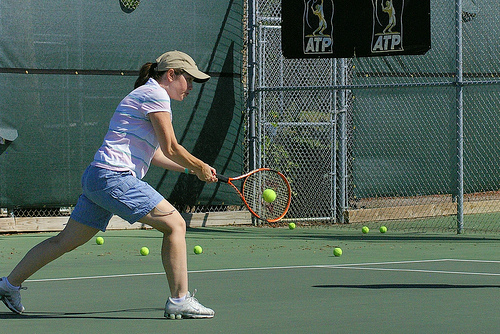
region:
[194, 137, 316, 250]
orange tennis racket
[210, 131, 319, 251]
orange tennis racket hitting tennis ball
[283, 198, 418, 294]
tennis balls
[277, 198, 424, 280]
tennis balls on tennis court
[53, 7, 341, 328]
woman tennis player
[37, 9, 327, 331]
woman hitting tennis balls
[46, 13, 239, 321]
woman wearing baseball hat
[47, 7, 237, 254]
woman wearing shorts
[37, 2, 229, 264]
woman wearing striped shirt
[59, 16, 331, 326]
woman tennis player wearing short sleaved shirt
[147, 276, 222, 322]
the shoe is white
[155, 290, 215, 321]
the shoe is on the court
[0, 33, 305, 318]
the woman is holding the racket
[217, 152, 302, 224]
the racket is red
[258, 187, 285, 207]
the ball is green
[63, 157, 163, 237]
the shorts are blue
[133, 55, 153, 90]
the hair is in a ponytail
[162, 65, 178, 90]
the girl has an ear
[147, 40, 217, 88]
the cap is brown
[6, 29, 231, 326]
the girl is wearing a cap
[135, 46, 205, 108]
the head of a woman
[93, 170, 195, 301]
the leg of a woman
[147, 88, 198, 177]
the arm of a woman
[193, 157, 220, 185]
the hands of a woman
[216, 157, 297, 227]
an orange tennis racket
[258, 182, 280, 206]
a green tennis ball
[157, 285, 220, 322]
a gray tennis shoe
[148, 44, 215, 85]
a tan baseball cap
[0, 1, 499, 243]
a gray chain link fence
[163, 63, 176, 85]
the ear of a woman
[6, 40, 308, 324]
woman playing tennis on court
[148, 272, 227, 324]
white tennis shoes on green court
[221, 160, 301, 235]
orange racket hitting ball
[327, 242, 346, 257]
bright green tennis ball on ground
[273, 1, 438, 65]
black banner on fence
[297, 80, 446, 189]
chain link fence around court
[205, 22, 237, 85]
shadow of chain link fence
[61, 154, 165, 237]
blue denim cargo shorts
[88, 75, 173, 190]
pink and white striped polo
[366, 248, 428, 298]
white painted lines on green court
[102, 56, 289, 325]
lady hitting a tennis ball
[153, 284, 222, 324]
lady wearing shoes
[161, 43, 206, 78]
lady wearing a brown hat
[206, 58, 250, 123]
a shadow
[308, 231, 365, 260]
tennis ball on the tennis court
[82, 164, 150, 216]
women wearing blue shorts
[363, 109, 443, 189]
a metal gate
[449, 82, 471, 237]
a metal pole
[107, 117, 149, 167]
lady wearing a stripped shirt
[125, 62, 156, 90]
hair is in a ponytail